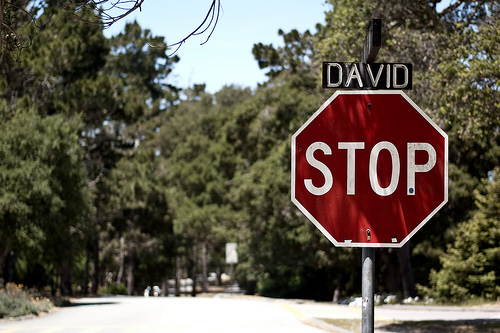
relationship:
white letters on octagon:
[303, 134, 437, 197] [291, 90, 450, 249]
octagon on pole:
[291, 90, 450, 249] [359, 248, 376, 331]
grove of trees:
[5, 4, 498, 308] [2, 4, 498, 304]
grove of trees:
[5, 4, 498, 308] [166, 106, 207, 137]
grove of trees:
[5, 4, 498, 308] [265, 153, 288, 190]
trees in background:
[146, 84, 250, 294] [26, 5, 468, 325]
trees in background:
[0, 89, 97, 306] [26, 5, 468, 325]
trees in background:
[65, 1, 173, 294] [26, 5, 468, 325]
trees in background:
[426, 166, 498, 300] [26, 5, 468, 325]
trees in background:
[218, 81, 288, 295] [26, 5, 468, 325]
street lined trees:
[2, 293, 498, 330] [2, 4, 498, 304]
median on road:
[300, 312, 498, 332] [0, 287, 497, 331]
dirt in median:
[379, 317, 440, 332] [284, 301, 499, 331]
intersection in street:
[35, 293, 358, 331] [4, 283, 334, 330]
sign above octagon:
[318, 61, 416, 91] [291, 90, 450, 249]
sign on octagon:
[318, 61, 416, 91] [291, 90, 450, 249]